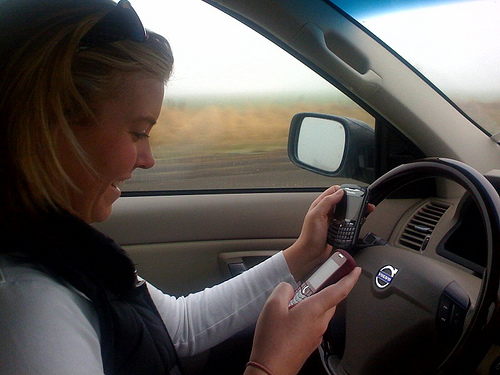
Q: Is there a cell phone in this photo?
A: Yes, there is a cell phone.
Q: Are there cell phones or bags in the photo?
A: Yes, there is a cell phone.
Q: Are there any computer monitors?
A: No, there are no computer monitors.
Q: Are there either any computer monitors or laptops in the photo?
A: No, there are no computer monitors or laptops.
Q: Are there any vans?
A: No, there are no vans.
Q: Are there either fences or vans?
A: No, there are no vans or fences.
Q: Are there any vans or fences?
A: No, there are no vans or fences.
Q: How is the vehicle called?
A: The vehicle is a car.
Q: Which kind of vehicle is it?
A: The vehicle is a car.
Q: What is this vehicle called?
A: That is a car.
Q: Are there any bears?
A: No, there are no bears.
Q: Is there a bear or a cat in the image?
A: No, there are no bears or cats.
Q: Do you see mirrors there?
A: Yes, there is a mirror.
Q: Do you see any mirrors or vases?
A: Yes, there is a mirror.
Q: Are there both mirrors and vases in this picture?
A: No, there is a mirror but no vases.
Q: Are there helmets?
A: No, there are no helmets.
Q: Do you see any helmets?
A: No, there are no helmets.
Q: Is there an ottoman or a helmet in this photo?
A: No, there are no helmets or ottomen.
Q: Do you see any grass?
A: Yes, there is grass.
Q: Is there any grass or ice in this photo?
A: Yes, there is grass.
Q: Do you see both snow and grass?
A: No, there is grass but no snow.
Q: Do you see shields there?
A: No, there are no shields.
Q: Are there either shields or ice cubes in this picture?
A: No, there are no shields or ice cubes.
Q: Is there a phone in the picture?
A: Yes, there is a phone.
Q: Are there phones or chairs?
A: Yes, there is a phone.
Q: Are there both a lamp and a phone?
A: No, there is a phone but no lamps.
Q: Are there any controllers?
A: No, there are no controllers.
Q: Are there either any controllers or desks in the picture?
A: No, there are no controllers or desks.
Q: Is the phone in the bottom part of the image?
A: Yes, the phone is in the bottom of the image.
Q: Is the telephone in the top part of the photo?
A: No, the telephone is in the bottom of the image.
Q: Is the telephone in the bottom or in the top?
A: The telephone is in the bottom of the image.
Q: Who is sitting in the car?
A: The girl is sitting in the car.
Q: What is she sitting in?
A: The girl is sitting in the car.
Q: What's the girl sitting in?
A: The girl is sitting in the car.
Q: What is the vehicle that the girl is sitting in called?
A: The vehicle is a car.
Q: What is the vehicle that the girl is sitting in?
A: The vehicle is a car.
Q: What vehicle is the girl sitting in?
A: The girl is sitting in the car.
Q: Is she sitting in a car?
A: Yes, the girl is sitting in a car.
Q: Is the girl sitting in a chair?
A: No, the girl is sitting in a car.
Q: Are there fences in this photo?
A: No, there are no fences.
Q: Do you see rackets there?
A: No, there are no rackets.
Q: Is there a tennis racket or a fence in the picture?
A: No, there are no rackets or fences.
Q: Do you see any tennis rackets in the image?
A: No, there are no tennis rackets.